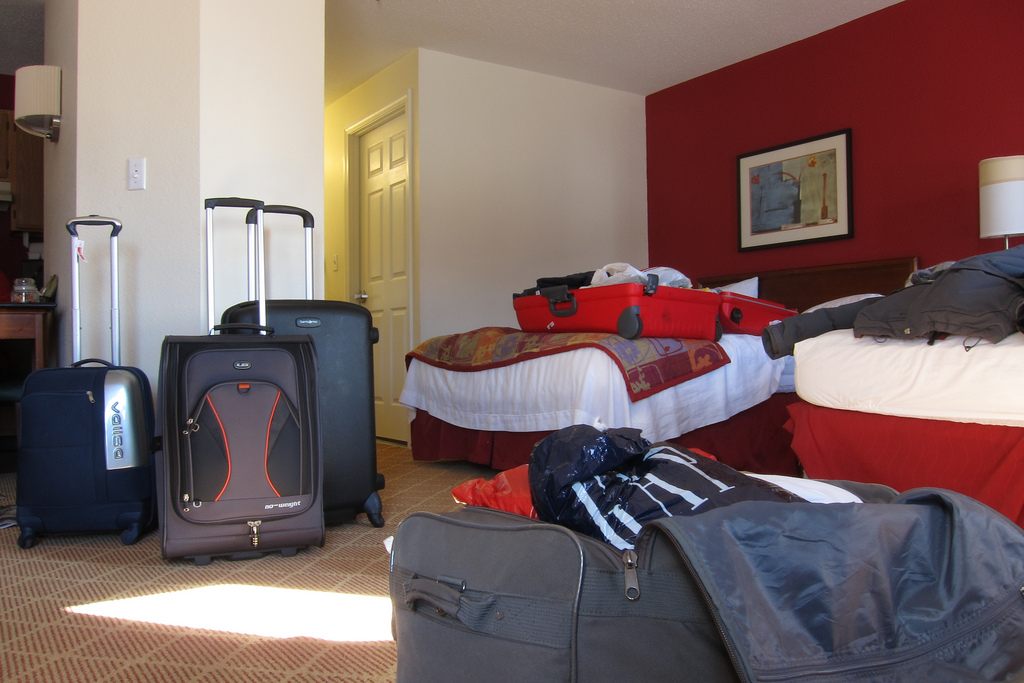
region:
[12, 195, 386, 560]
Three standing suitcases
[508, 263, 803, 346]
Open red suitcase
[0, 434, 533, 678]
Red and tan carpet flooring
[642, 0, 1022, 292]
Red accent wall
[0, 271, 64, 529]
Wooden desk with a jar on it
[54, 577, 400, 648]
Beam of sunlight on the floor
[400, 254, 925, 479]
Patterned blanket on bed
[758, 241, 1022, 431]
Grey jacket on mattress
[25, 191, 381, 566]
suitcases with long handles against a wall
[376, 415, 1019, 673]
soft luggage with unzipped flap showing bags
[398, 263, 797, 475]
red suitcase open flat on top of bed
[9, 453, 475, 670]
red and yellow carpet of woven squares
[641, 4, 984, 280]
framed abstract art hanging on surface of wall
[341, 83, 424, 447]
white door with square and rectangular panels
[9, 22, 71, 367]
lighting fixture attached to wall above wooden table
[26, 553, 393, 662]
patch of bright light falling across carpeting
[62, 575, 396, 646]
Sunlight filtering through a window reflected on the carpet.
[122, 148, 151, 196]
A white light switch attached to the wall.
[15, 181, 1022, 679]
A hotel room filled with luggage.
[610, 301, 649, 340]
A black wheel attached to luggage.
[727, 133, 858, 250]
A painting hanging from the wall.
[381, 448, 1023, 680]
A opened grey duffle bag with contents spilling out.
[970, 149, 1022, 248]
A brown and white lamp shade.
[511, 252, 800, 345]
An opened red suitcase.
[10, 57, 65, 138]
A white lighting sconce.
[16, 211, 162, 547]
smallest navy blue luggage with handle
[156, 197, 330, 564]
medium gray and red luggage with handle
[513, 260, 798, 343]
bright red luggage laying on bed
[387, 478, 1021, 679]
gray duffel bag on floor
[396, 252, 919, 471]
hotel bed with red bed skirt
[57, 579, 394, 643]
sunlight shining on carpeted floor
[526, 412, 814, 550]
black and white plastic GAP bag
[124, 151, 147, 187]
light switch on white wall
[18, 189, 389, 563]
Three suitcases standing upright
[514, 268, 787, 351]
Red suitcase on the bed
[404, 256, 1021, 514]
Two beds in the room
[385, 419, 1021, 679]
Clothes in an open duffel bag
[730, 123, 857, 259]
Picture on the wall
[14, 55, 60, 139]
Light fixture on the wall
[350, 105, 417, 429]
White door in the hallway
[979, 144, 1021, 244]
Tan and white lampshade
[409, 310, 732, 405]
Blanket on the bed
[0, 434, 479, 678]
Carpeting on the floor